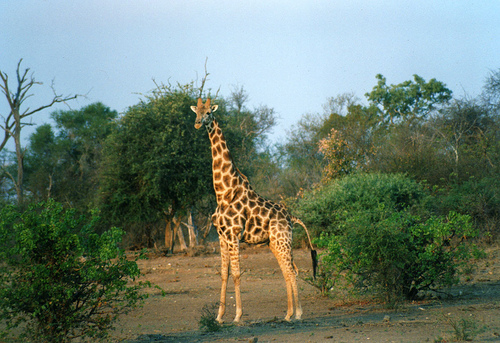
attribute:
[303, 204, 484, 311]
bush — green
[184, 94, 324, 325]
giraffe — brown, tan, tall, standing, spotted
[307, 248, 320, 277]
hair — black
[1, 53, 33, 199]
tree — dead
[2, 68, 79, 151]
tree — dead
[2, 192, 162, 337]
tree — small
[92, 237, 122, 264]
leaves — green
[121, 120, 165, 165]
leaves — green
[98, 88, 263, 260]
tree — dense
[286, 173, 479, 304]
tree — small, dense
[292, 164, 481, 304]
bush — green, leafy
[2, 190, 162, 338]
bush — green, leafy, lush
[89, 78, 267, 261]
tree — green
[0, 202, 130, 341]
bush — leafy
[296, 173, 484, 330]
bush — leafy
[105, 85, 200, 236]
tree — leafy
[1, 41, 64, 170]
tree — bare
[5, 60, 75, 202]
tree — leafless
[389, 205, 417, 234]
leafs — green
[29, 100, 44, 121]
branches — tree, brown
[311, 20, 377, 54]
sky — blue, clear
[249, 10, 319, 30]
clouds — light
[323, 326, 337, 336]
rocks — small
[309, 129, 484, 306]
bushes — several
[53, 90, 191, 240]
trees — several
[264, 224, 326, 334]
legs — back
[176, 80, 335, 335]
giraffe — big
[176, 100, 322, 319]
giraffe — brown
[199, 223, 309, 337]
legs — long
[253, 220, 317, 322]
legs — back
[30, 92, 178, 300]
trees — green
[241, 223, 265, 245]
belly — bulky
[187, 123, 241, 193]
neck — long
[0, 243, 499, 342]
dirt — brown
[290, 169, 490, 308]
bush — green, lush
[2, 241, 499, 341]
field — dirt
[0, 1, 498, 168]
sky — clear, blue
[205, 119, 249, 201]
neck — long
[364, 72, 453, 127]
tree — leafy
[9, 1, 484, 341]
scene —  day time, field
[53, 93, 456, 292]
bushes — heavy green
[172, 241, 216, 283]
ground — grass-less 